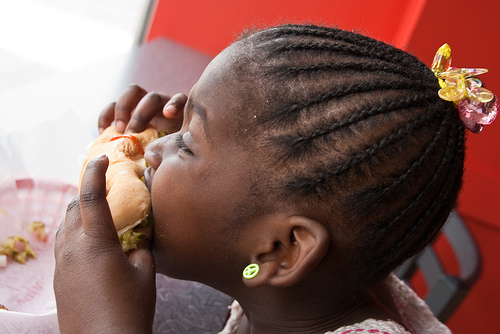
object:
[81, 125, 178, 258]
food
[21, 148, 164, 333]
girl's hand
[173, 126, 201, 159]
eye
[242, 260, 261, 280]
earring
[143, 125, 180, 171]
nose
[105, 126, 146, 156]
ketchup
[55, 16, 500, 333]
girl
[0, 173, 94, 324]
food basket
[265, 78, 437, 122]
braid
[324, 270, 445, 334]
clothes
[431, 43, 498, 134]
barrette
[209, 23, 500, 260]
girl's hair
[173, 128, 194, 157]
eyelash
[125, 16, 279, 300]
girl's face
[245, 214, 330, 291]
ear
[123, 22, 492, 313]
girl's head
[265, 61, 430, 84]
braid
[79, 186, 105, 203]
knuckles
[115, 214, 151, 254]
relish